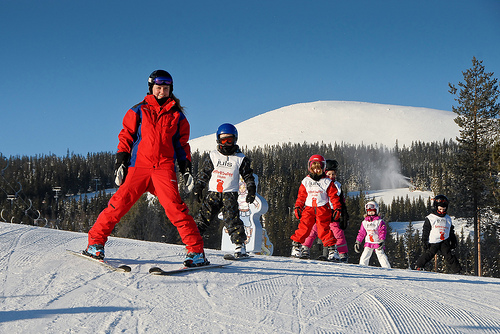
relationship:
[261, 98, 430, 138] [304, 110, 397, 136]
mountain covered in snow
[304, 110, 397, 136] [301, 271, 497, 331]
snow has tracks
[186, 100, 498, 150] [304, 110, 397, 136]
hillside has snow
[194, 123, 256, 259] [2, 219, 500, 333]
child on a slope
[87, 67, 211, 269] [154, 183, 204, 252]
skier has a leg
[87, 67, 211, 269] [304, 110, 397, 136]
skier in snow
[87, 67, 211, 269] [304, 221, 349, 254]
skier wearing pink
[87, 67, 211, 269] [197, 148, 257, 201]
skier wearing black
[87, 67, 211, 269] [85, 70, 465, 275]
skier in a group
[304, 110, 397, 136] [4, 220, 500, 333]
snow on ground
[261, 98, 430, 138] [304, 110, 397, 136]
mountain covered with snow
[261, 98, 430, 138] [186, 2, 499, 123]
mountain in background